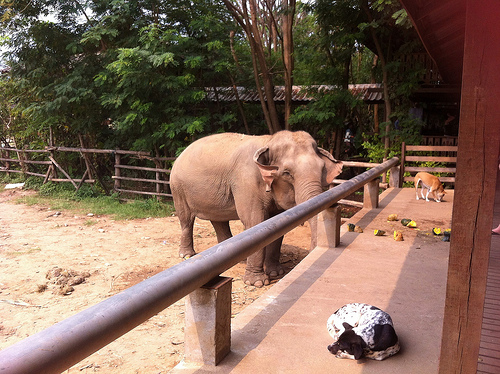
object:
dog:
[326, 303, 401, 361]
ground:
[99, 233, 130, 267]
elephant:
[169, 130, 343, 288]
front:
[171, 157, 402, 372]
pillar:
[437, 0, 500, 374]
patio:
[167, 187, 454, 374]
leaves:
[92, 72, 107, 81]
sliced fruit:
[432, 227, 441, 235]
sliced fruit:
[354, 225, 363, 233]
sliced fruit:
[387, 213, 398, 220]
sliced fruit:
[374, 229, 386, 236]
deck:
[168, 187, 454, 374]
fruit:
[374, 229, 386, 236]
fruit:
[401, 218, 416, 227]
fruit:
[395, 232, 405, 241]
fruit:
[432, 228, 441, 236]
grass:
[111, 205, 132, 220]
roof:
[203, 84, 381, 101]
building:
[193, 83, 386, 136]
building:
[397, 0, 500, 374]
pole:
[1, 157, 400, 371]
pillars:
[183, 276, 234, 367]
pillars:
[316, 205, 341, 248]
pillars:
[363, 178, 379, 208]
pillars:
[389, 165, 401, 188]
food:
[348, 214, 451, 242]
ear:
[252, 145, 279, 193]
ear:
[316, 147, 344, 187]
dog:
[414, 172, 448, 203]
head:
[437, 191, 448, 201]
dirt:
[0, 183, 311, 374]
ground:
[27, 221, 48, 252]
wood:
[0, 147, 174, 197]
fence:
[0, 124, 382, 222]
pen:
[0, 157, 401, 374]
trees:
[0, 0, 427, 198]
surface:
[0, 219, 144, 374]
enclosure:
[0, 177, 312, 370]